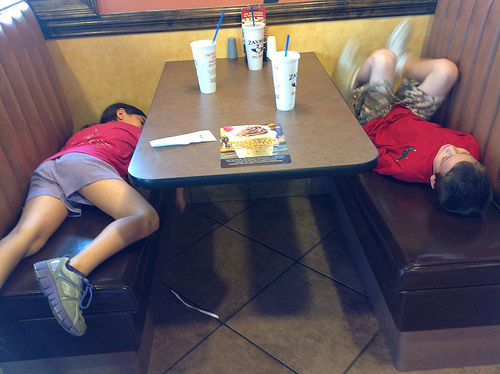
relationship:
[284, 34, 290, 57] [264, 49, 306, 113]
straw in cup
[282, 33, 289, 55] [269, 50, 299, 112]
straw on cup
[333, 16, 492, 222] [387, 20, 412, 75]
boy on shoes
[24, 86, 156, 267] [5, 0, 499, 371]
child laying in booth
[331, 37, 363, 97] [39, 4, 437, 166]
foot on wall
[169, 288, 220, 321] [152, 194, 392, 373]
paper on floor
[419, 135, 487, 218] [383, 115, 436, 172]
boy wearing red shirt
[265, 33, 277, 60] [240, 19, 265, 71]
salt shaker near cup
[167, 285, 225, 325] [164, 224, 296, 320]
paper on brown tile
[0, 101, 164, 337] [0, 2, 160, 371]
child sleeping on seat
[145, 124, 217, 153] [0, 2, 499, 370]
bill on table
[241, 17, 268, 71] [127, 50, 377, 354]
cup on table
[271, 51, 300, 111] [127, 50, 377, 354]
cup on table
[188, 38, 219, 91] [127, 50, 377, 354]
cup on table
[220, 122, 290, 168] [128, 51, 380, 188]
menu on brown table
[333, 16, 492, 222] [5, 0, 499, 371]
boy on booth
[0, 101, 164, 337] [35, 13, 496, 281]
child on booth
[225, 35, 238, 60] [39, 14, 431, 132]
pepper set wall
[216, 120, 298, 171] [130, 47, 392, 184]
advertisement on table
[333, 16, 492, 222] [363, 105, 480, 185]
boy wears a red shirt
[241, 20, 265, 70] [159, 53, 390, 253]
cup on table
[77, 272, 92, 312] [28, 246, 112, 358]
laces in sneakers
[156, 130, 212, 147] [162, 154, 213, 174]
receipt laying table